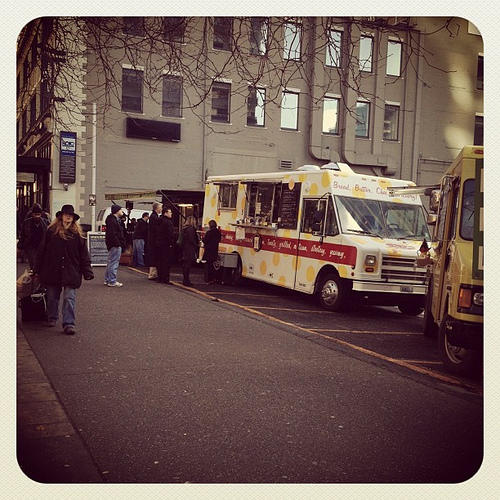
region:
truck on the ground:
[188, 154, 443, 324]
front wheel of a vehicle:
[306, 257, 352, 317]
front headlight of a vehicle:
[359, 248, 379, 276]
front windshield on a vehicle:
[331, 186, 435, 251]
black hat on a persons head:
[52, 199, 84, 224]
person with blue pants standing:
[99, 196, 131, 293]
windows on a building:
[349, 93, 408, 149]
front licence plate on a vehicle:
[393, 278, 418, 298]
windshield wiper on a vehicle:
[340, 223, 389, 248]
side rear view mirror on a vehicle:
[423, 169, 458, 253]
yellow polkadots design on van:
[253, 251, 310, 286]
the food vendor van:
[189, 158, 433, 325]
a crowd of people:
[92, 191, 199, 276]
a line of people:
[94, 196, 215, 291]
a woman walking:
[35, 192, 105, 347]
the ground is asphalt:
[140, 309, 310, 456]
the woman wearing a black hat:
[54, 195, 79, 232]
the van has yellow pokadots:
[183, 153, 428, 328]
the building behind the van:
[116, 40, 321, 171]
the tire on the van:
[306, 270, 357, 320]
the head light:
[361, 248, 379, 273]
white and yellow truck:
[202, 161, 430, 311]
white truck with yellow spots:
[197, 165, 420, 300]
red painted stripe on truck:
[196, 219, 360, 274]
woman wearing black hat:
[49, 198, 89, 320]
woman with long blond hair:
[41, 210, 91, 325]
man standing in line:
[100, 203, 130, 283]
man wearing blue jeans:
[102, 206, 124, 286]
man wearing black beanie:
[102, 200, 125, 285]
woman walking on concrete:
[45, 205, 90, 337]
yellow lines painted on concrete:
[239, 298, 429, 388]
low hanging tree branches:
[82, 32, 378, 115]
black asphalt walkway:
[175, 367, 380, 489]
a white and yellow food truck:
[171, 140, 438, 339]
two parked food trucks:
[225, 147, 480, 390]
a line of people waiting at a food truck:
[110, 174, 229, 283]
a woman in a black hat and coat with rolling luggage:
[32, 203, 89, 328]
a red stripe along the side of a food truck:
[220, 221, 375, 278]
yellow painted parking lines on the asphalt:
[275, 297, 377, 377]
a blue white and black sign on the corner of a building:
[57, 130, 82, 188]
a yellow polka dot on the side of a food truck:
[266, 254, 285, 265]